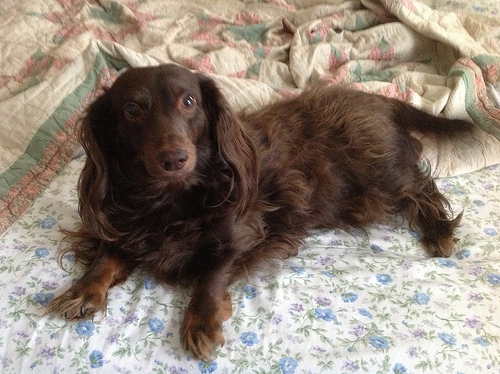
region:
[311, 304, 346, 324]
blue flower on sheet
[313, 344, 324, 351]
purple flower on sheet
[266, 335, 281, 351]
green leaves on sheet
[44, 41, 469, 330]
brown dog on bed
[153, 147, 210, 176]
heart shaped dog nose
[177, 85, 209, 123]
brown dog eyes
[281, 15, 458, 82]
rumpled quilt on bed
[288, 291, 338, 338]
bouquet flower pattern on bed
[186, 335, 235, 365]
dog paw on bed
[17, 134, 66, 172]
green and pink border on quilt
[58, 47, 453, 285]
the dog is brown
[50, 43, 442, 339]
the dog is furry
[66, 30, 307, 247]
the dog has two eyes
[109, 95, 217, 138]
dog's eyes are brown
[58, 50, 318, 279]
the dog has nose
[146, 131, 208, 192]
dog's nose is brown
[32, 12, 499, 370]
the dog is on the bed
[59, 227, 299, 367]
the dog's nails are black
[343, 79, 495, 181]
the tail is short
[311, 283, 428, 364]
the flowers are blue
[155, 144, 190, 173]
Dark brown nose of a dog.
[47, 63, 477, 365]
Dark brown little dog lying on a bed.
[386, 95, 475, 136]
Little dark brown tail of a dog.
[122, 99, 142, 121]
Right eye of a dog lying on a bed.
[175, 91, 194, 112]
Dog lying on the beds left eye.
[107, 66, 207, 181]
Head of a little brown dog.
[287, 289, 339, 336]
Group of blue and purple flowers on a bed.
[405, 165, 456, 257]
Back left food of a brown dog.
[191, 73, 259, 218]
The dog's left brown ear.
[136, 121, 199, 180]
Snout of a brown dog lying on a bed.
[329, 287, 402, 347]
part of a sheet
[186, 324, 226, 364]
left leg of a dog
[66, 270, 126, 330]
right leg of the dog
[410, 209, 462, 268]
hind leg of the dog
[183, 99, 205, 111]
left eye of the dog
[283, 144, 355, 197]
stomach of the dog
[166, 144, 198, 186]
nose of the dog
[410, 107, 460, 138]
tail of the dog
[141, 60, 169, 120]
head of the dog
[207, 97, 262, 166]
ear of the dog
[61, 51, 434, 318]
long haired dachshund on a bed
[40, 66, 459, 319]
small brown dog with long hair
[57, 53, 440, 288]
small dog with long ears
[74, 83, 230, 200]
face of long haired dachshund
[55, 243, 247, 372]
paws of long haired dog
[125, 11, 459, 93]
rumpled quilt on bed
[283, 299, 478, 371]
floral pattern on bed covers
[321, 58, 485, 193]
fluffy brown dog tail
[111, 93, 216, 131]
brown eyes on a brown dog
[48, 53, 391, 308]
fluffy dog looks at camera